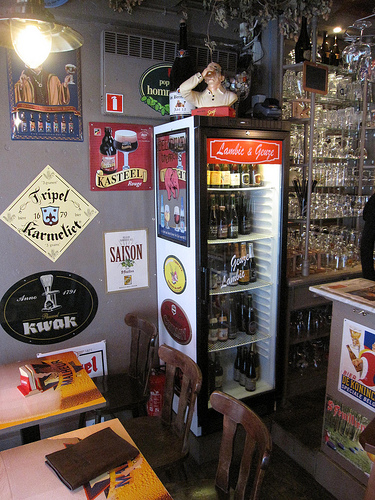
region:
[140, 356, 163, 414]
Fire extinguisher next to fridge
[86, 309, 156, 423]
Wooden chair next to fridge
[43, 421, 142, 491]
Brown notebook on table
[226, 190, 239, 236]
Beer bottle in fridge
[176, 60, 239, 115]
Sculpture on top of fridge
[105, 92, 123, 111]
Fire extinguisher sticker on top of poster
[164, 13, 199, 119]
Large bottle next to sculpture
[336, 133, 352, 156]
Wine glass on shelf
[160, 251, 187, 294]
Magnet poster on fridge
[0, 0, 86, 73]
Lamp above wooden table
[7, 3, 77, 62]
light in the left corner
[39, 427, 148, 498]
book on the table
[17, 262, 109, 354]
black "kwak" sign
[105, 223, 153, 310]
white and brown saison sign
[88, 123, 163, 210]
red and white kasteel sign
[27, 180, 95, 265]
creme colored tripel karmeliet sign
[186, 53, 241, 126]
stature of man waring white shirt on top of beverage fridge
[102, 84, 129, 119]
fire extinguisher sign above kasteel sign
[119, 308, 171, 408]
brown chair closest to wall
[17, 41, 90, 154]
blue poster partially covered by light in left corner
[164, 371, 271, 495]
a pair of wooden chairs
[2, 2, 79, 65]
a very potent light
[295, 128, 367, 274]
a lot of wine cups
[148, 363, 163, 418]
a red extinguisher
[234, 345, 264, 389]
several bottles of wine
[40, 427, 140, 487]
a brown book on the table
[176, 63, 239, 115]
a human figure drinking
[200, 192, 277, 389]
a cooler full of drinks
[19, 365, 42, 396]
a package of napkins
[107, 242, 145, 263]
the word SAISON in red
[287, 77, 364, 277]
Clear glasses on shelves.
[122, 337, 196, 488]
Brown wooden chair at table.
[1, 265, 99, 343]
Black oval sign on wall.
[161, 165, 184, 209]
Pink elephant on sign.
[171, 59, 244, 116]
Bust of man drinking.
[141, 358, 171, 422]
Red fire extinguisher on floor.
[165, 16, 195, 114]
Large wine bottle on refrigerator unit.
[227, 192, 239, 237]
Bottle of beer on shelf.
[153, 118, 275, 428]
Refrigerator unit for drinks.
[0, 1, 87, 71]
Light fixture hanging from ceiling.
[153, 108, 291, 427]
A refrigerator for alcoholic beverages.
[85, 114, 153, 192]
A picture of Kasteel.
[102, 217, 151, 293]
A poster that says Saison.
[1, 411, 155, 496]
A small table made of wood.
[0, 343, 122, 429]
Another small wood table.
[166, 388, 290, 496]
The chair is made of wood.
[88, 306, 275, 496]
Three chairs next to each other.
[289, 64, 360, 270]
Glasses on the shelves.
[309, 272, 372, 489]
The counter is next to the glasses.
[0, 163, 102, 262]
A poster that says Tripel Karmliet.